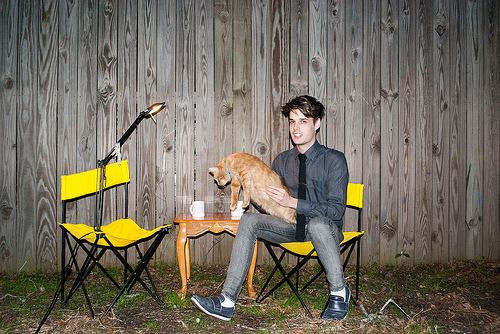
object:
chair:
[60, 159, 172, 319]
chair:
[251, 182, 364, 320]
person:
[190, 95, 353, 322]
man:
[190, 95, 351, 322]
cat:
[208, 152, 298, 224]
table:
[175, 212, 258, 302]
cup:
[189, 201, 205, 218]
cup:
[230, 200, 249, 216]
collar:
[224, 157, 232, 177]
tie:
[295, 153, 307, 242]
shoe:
[190, 292, 237, 323]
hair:
[281, 95, 325, 134]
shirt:
[269, 140, 349, 231]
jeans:
[221, 212, 347, 303]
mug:
[189, 201, 204, 218]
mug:
[230, 201, 247, 217]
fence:
[1, 1, 498, 274]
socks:
[220, 287, 346, 308]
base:
[252, 231, 364, 318]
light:
[94, 101, 166, 236]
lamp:
[95, 102, 166, 235]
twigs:
[0, 280, 414, 334]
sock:
[219, 292, 235, 308]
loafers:
[190, 286, 352, 322]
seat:
[58, 217, 172, 250]